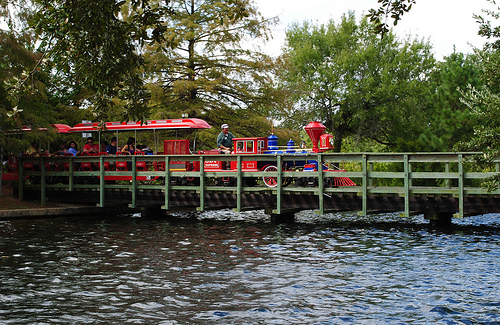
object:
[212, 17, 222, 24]
leaves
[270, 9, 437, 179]
trees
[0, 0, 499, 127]
sky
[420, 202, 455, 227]
bridge supports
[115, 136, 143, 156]
passenger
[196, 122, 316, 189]
engine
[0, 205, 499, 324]
water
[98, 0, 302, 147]
tree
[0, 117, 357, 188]
train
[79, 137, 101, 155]
people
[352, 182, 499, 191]
tracks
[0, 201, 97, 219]
bank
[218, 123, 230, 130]
cap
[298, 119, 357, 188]
cowcatcher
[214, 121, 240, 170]
man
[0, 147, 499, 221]
bridge